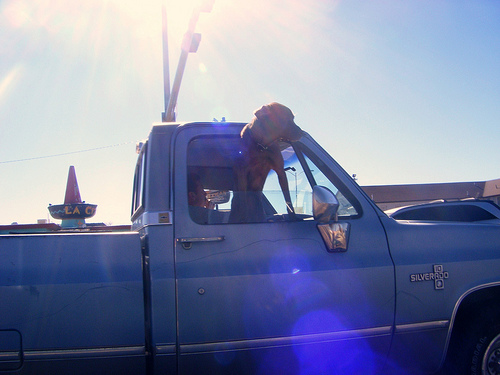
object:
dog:
[234, 98, 312, 225]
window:
[187, 131, 365, 226]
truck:
[0, 112, 500, 375]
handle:
[174, 236, 225, 252]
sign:
[46, 162, 102, 234]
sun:
[0, 0, 337, 66]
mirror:
[308, 183, 356, 257]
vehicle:
[378, 193, 500, 225]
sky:
[0, 0, 497, 226]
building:
[337, 170, 500, 211]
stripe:
[0, 317, 450, 367]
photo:
[0, 1, 500, 375]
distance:
[0, 1, 499, 231]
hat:
[47, 161, 100, 219]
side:
[0, 116, 500, 375]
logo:
[407, 253, 450, 298]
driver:
[187, 167, 237, 226]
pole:
[144, 1, 220, 125]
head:
[235, 98, 309, 145]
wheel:
[451, 316, 500, 375]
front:
[385, 209, 499, 374]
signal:
[155, 0, 221, 126]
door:
[168, 112, 400, 375]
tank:
[0, 323, 23, 371]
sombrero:
[47, 164, 99, 225]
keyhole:
[196, 287, 207, 296]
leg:
[275, 151, 304, 218]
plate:
[408, 261, 451, 293]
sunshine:
[1, 1, 500, 174]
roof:
[360, 176, 499, 204]